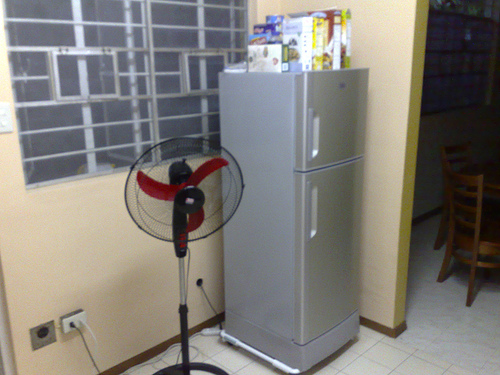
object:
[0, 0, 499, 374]
kitchen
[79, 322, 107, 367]
cable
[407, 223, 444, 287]
ground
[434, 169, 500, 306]
chairs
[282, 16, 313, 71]
packet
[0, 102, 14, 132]
switch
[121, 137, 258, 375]
air fan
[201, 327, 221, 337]
surge protector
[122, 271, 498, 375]
floor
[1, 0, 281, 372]
wall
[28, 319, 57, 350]
outlets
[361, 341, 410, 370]
tile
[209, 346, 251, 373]
tile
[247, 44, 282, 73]
boxes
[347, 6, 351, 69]
boxes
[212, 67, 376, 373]
fridge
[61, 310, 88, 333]
socket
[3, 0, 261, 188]
window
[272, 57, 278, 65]
cereal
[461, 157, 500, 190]
table